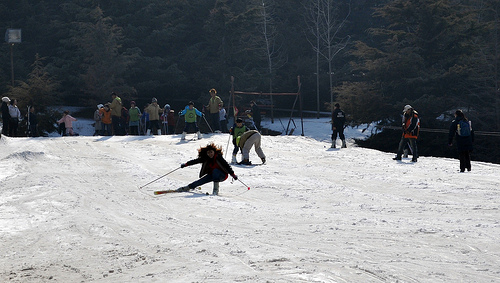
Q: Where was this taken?
A: A ski school.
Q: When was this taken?
A: During the day.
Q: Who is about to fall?
A: The woman dressed in black.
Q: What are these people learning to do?
A: To ski.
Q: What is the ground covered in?
A: Snow.